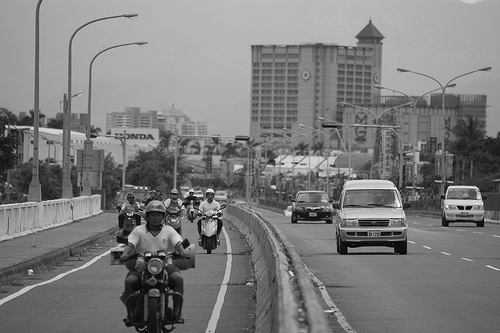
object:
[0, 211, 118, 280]
lane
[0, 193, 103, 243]
railing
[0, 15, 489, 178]
building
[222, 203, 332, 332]
barrier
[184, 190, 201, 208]
man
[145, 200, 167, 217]
helmet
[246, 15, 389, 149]
house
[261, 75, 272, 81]
windows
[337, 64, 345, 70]
windows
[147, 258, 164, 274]
headlight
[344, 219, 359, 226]
headlight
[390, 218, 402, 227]
headlight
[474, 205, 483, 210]
headlight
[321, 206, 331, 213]
headlight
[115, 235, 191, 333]
bike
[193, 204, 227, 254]
bike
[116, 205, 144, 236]
bike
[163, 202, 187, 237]
bike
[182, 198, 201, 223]
bike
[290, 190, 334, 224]
black car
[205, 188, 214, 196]
helmet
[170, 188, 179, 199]
helmet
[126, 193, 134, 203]
helmet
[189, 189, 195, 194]
helmet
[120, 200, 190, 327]
man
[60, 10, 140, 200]
post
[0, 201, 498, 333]
road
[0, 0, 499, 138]
sky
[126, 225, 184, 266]
pullover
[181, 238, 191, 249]
mirror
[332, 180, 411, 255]
car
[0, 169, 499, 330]
street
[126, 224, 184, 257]
shirt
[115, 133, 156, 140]
honda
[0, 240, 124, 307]
line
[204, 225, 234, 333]
line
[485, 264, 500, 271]
lines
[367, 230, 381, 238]
license plate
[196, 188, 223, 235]
man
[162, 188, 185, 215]
man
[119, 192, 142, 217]
man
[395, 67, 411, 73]
light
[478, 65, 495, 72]
light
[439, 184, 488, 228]
vehicle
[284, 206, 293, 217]
vehicle